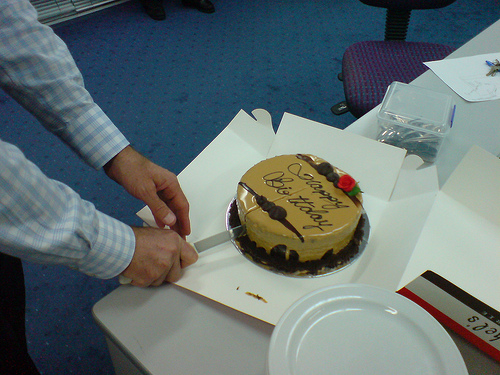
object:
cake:
[224, 151, 372, 278]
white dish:
[228, 208, 372, 279]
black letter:
[303, 218, 339, 233]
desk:
[88, 18, 495, 370]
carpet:
[0, 3, 427, 372]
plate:
[267, 283, 468, 372]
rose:
[336, 172, 355, 192]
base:
[227, 200, 372, 275]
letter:
[264, 170, 293, 196]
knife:
[173, 214, 270, 282]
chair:
[329, 0, 474, 127]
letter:
[318, 190, 338, 205]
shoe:
[143, 3, 168, 20]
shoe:
[181, 0, 221, 17]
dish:
[270, 285, 468, 374]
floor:
[3, 1, 498, 369]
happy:
[290, 160, 351, 215]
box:
[108, 103, 498, 356]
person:
[0, 1, 195, 372]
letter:
[283, 160, 318, 180]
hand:
[114, 221, 242, 294]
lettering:
[267, 160, 352, 233]